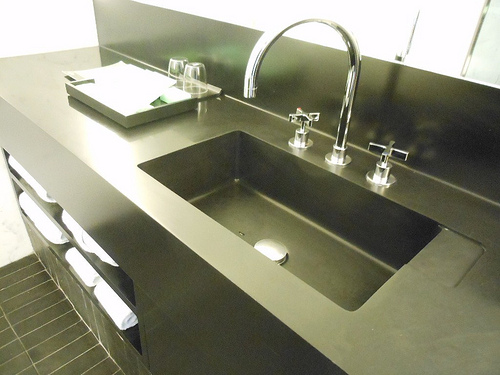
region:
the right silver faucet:
[366, 133, 410, 185]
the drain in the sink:
[251, 235, 293, 264]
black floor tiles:
[0, 256, 126, 373]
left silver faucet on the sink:
[288, 106, 320, 155]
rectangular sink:
[132, 128, 454, 315]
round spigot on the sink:
[240, 6, 361, 174]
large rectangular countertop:
[2, 44, 498, 374]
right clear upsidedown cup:
[181, 57, 210, 92]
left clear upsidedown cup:
[166, 51, 196, 84]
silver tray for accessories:
[63, 57, 220, 129]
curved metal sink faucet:
[237, 5, 363, 175]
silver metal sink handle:
[363, 136, 410, 191]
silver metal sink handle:
[285, 104, 322, 153]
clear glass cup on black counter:
[181, 60, 210, 97]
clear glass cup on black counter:
[165, 53, 193, 93]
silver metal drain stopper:
[249, 236, 292, 268]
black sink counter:
[0, 0, 499, 373]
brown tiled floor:
[0, 211, 158, 373]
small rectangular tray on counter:
[63, 60, 205, 130]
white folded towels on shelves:
[5, 151, 140, 331]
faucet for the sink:
[223, 6, 365, 177]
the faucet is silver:
[243, 11, 357, 177]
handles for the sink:
[363, 128, 408, 208]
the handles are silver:
[368, 126, 417, 214]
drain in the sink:
[245, 216, 295, 308]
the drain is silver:
[247, 208, 282, 284]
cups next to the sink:
[156, 36, 222, 121]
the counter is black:
[13, 85, 145, 242]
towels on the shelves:
[28, 194, 165, 374]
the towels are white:
[27, 183, 136, 326]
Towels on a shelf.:
[6, 153, 137, 331]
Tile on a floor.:
[0, 253, 127, 374]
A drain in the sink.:
[254, 235, 289, 265]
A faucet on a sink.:
[242, 12, 409, 189]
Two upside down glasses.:
[166, 54, 206, 96]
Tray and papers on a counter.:
[63, 60, 198, 131]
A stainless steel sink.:
[135, 128, 444, 313]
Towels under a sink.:
[7, 155, 137, 332]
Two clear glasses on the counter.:
[166, 53, 209, 94]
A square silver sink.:
[136, 128, 443, 315]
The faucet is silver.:
[232, 11, 405, 188]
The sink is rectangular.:
[116, 89, 448, 319]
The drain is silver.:
[246, 234, 286, 264]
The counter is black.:
[32, 41, 492, 363]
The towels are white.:
[4, 150, 159, 346]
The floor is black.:
[4, 249, 110, 371]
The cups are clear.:
[152, 43, 230, 126]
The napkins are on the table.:
[66, 48, 230, 126]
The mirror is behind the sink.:
[222, 0, 493, 84]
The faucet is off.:
[230, 16, 414, 220]